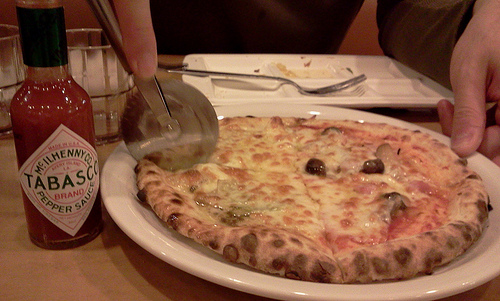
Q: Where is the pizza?
A: On a plate.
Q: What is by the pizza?
A: A jar of tabasco sauce by the pizza.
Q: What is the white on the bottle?
A: A label on the bottle.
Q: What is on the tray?
A: A fork on the tray.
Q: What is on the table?
A: Full bottle of Tabasco sauce.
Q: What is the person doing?
A: Person slicing a whole pizza.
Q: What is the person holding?
A: Silver round pizza cutter.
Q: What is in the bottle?
A: Hot sauce.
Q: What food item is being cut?
A: A pizza.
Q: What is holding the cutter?
A: A hand.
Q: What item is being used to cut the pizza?
A: A pizza cutter.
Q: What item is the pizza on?
A: A plate.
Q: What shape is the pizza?
A: Circle.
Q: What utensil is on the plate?
A: A fork.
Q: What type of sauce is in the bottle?
A: Hot sauce.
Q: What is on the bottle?
A: A label.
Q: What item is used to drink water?
A: A glass.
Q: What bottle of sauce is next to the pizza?
A: Tabasco hot sauce.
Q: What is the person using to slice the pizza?
A: A pizza cutter.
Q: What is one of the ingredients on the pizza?
A: Cheese.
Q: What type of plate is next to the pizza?
A: A white plate with dividers.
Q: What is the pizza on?
A: A large white plate.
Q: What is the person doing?
A: Cutting pizza into halves.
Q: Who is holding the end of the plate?
A: The person cutting the pizza.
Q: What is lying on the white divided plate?
A: A eating utensil.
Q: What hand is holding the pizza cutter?
A: The right hand.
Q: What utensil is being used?
A: A pizza cutter.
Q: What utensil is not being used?
A: A fork.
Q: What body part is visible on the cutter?
A: A finger.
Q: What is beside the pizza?
A: Tabasco sauce.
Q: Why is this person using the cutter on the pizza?
A: To cut pizza slices.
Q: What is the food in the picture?
A: Pizza.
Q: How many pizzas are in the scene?
A: One.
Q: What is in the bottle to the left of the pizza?
A: Hot sauce.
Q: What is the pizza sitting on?
A: White plate.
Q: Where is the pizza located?
A: Restaurant.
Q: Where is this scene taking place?
A: In a restaurant.